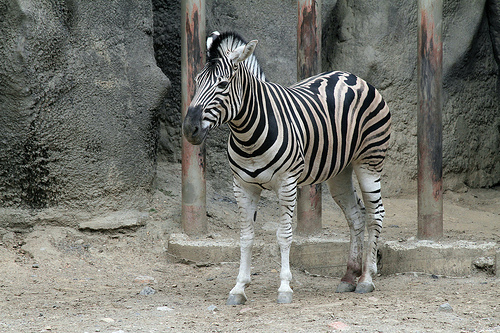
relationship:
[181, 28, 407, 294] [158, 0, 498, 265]
zebra standing in front of bars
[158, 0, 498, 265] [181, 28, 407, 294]
bars behind zebra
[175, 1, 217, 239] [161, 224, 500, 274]
pole in base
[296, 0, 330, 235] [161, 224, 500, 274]
pole in base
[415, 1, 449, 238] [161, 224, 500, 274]
pole in base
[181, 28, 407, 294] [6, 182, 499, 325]
zebra standing on floor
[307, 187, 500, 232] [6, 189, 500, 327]
patch on ground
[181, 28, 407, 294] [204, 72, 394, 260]
zebra has skin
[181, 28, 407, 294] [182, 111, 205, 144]
zebra has nose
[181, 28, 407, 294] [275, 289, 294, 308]
zebra has foot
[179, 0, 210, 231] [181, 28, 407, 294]
pillar behind zebra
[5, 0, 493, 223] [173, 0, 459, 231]
rocks behind pillars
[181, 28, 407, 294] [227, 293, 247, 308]
zebra has foot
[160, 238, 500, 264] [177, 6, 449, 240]
stone underneath pillars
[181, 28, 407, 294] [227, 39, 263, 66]
zebra has ear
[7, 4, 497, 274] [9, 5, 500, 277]
wall in background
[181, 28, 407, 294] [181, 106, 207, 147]
zebra has snout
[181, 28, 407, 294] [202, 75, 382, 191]
zebra with stripes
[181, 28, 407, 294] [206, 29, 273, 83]
zebra has mane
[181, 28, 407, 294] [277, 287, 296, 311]
zebra has hoof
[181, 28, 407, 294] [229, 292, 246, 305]
zebra has hoof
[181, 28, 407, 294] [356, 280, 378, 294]
zebra has hoof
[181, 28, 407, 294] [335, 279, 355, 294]
zebra has hoof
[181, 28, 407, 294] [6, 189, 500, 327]
zebra on ground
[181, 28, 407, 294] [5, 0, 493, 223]
zebra beside rocks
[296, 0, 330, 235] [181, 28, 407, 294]
pole behind zebra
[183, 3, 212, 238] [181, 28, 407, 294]
pole behind zebra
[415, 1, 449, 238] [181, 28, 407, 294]
pole behind zebra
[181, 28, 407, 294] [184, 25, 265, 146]
zebra has head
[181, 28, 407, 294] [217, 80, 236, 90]
zebra has eye